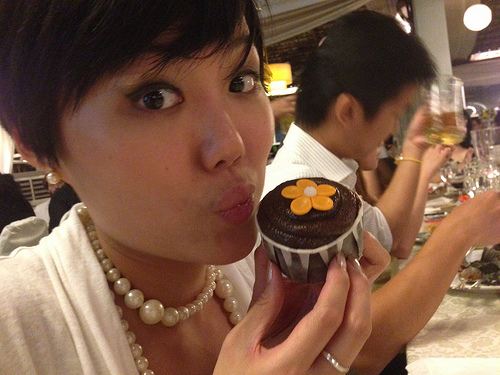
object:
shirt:
[232, 116, 399, 318]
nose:
[196, 98, 247, 172]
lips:
[210, 182, 255, 226]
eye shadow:
[126, 81, 181, 101]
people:
[0, 0, 378, 375]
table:
[398, 284, 500, 374]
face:
[40, 7, 281, 267]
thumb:
[217, 261, 287, 363]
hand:
[210, 250, 377, 375]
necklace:
[73, 206, 250, 375]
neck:
[94, 225, 209, 302]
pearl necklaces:
[137, 295, 167, 327]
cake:
[253, 175, 365, 287]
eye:
[126, 79, 188, 115]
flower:
[280, 178, 337, 216]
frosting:
[279, 177, 338, 217]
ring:
[320, 347, 351, 373]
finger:
[267, 250, 354, 375]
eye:
[224, 68, 261, 100]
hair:
[0, 0, 272, 170]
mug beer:
[420, 108, 469, 146]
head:
[293, 9, 441, 162]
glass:
[425, 75, 468, 148]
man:
[258, 3, 459, 375]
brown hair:
[286, 7, 441, 132]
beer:
[438, 163, 471, 204]